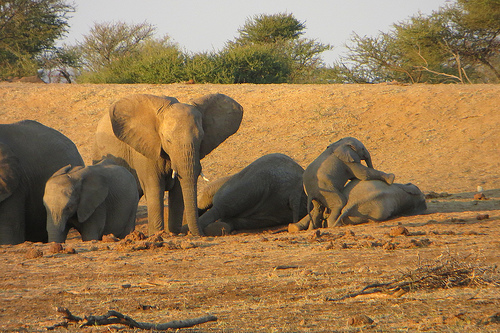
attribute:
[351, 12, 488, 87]
tree — in the background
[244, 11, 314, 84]
tree — in the background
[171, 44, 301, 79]
tree — in the background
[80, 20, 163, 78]
tree — in the background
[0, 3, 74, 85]
tree — in the background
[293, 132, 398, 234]
elephant — small, baby 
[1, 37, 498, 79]
trees — of Africa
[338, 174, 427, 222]
elephant — in the shot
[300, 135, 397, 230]
elephant — in the shot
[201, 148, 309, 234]
elephant — in the shot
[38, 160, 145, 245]
elephant — in the shot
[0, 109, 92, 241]
elephant — in the shot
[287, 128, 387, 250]
elephant — playing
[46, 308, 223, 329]
branch — broken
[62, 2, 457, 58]
sky — blue , in daytime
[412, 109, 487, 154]
dirt — ground, dusty, brown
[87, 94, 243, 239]
elephant — in the shot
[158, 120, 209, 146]
eyes — closed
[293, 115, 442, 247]
elephants — Baby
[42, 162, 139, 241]
elephant — family, relaxing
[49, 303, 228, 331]
stick — broken, dried up 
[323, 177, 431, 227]
elephant — reclined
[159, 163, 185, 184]
tusk — white,  ivory  , elephant's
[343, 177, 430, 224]
elephant — outdoors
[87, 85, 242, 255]
elephant — larger, family, relaxing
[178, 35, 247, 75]
leaves — green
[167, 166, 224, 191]
trunks — white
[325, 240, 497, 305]
branches — in the shot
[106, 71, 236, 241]
big elephant — full grown, male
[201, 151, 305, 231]
elephant — family, relaxing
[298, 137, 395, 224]
elephant — family, relaxing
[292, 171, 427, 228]
elephant — family, relaxing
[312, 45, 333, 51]
leaves — green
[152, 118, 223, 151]
eyes — closed